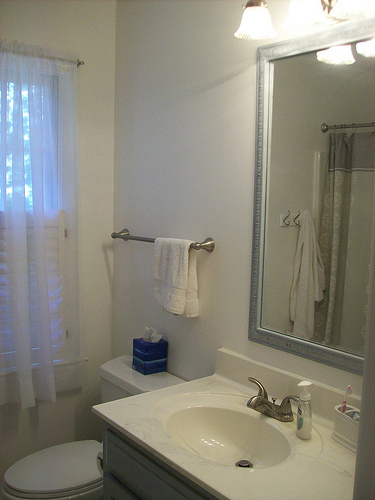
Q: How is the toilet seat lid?
A: Down.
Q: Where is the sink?
A: In the bathroom.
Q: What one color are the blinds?
A: White.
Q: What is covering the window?
A: Curtains.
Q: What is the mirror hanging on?
A: The wall.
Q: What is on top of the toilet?
A: A tissue box.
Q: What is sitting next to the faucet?
A: Soap.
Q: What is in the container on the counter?
A: A toothbrush.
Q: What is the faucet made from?
A: Metal.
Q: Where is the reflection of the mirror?
A: Opposite wall.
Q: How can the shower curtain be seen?
A: In mirror.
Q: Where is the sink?
A: Under mirror.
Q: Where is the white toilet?
A: Bathroom.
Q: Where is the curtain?
A: Window.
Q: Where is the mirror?
A: Wall.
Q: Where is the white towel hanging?
A: On rod in bathroom.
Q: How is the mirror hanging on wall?
A: It is affixed.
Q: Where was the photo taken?
A: In a bathroom.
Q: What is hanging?
A: A towel.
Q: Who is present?
A: No one.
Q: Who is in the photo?
A: Nobody.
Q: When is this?
A: Daytime.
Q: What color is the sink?
A: White.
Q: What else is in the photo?
A: Mirror.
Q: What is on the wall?
A: Bar.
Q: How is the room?
A: Neat.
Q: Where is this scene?
A: In a bathroom.